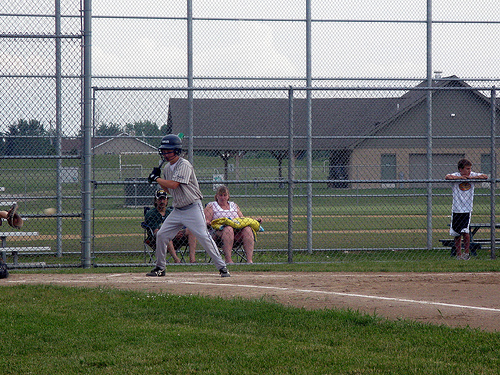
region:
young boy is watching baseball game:
[428, 144, 499, 261]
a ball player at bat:
[111, 80, 236, 287]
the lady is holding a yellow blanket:
[203, 181, 268, 259]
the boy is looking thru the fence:
[431, 157, 493, 247]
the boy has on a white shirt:
[424, 142, 489, 252]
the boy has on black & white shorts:
[449, 191, 487, 251]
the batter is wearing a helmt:
[140, 125, 242, 295]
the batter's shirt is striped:
[127, 131, 230, 291]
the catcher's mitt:
[7, 198, 33, 235]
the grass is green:
[55, 307, 192, 358]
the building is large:
[304, 61, 490, 183]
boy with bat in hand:
[145, 129, 231, 286]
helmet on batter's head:
[149, 129, 187, 157]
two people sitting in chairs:
[132, 183, 272, 265]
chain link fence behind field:
[281, 121, 386, 255]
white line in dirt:
[271, 282, 396, 308]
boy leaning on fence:
[432, 153, 488, 257]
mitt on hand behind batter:
[5, 197, 30, 237]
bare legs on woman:
[217, 222, 265, 266]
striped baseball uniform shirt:
[160, 160, 200, 217]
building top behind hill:
[47, 124, 153, 155]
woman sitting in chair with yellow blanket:
[203, 182, 276, 276]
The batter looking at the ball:
[144, 129, 232, 276]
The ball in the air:
[38, 202, 58, 219]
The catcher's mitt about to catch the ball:
[3, 200, 25, 232]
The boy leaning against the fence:
[446, 150, 493, 267]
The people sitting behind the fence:
[137, 184, 269, 269]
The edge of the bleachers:
[0, 182, 51, 270]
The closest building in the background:
[164, 61, 496, 185]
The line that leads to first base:
[185, 280, 499, 317]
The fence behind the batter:
[3, 0, 499, 274]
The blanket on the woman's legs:
[208, 213, 265, 235]